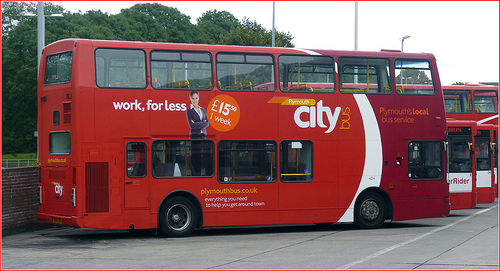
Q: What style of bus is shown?
A: Double decker.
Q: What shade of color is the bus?
A: Red.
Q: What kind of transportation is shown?
A: Bus.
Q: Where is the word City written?
A: On side of bus.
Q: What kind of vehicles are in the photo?
A: Red double decker buses.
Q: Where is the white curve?
A: Side of front bus.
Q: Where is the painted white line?
A: On concrete, right of buses.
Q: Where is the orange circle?
A: Side of bus, between two levels of windows.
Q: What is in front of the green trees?
A: Gray street lamps.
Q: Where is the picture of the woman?
A: Left of orange circle.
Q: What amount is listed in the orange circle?
A: 15 pounds per week.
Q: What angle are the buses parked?
A: Diagonally.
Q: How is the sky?
A: Sunny, clear, and white.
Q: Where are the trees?
A: Behind the buses.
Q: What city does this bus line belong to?
A: Plymouth.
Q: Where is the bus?
A: Parked in a lot.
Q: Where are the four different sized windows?
A: On the lower deck of the bus.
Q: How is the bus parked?
A: At an angle.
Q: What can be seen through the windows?
A: Chair tops.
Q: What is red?
A: Buses.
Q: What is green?
A: Trees.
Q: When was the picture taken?
A: Daytime.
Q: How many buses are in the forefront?
A: One.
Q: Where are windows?
A: On a bus.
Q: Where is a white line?
A: On the ground.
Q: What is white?
A: Sky.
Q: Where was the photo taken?
A: In a parking lot.